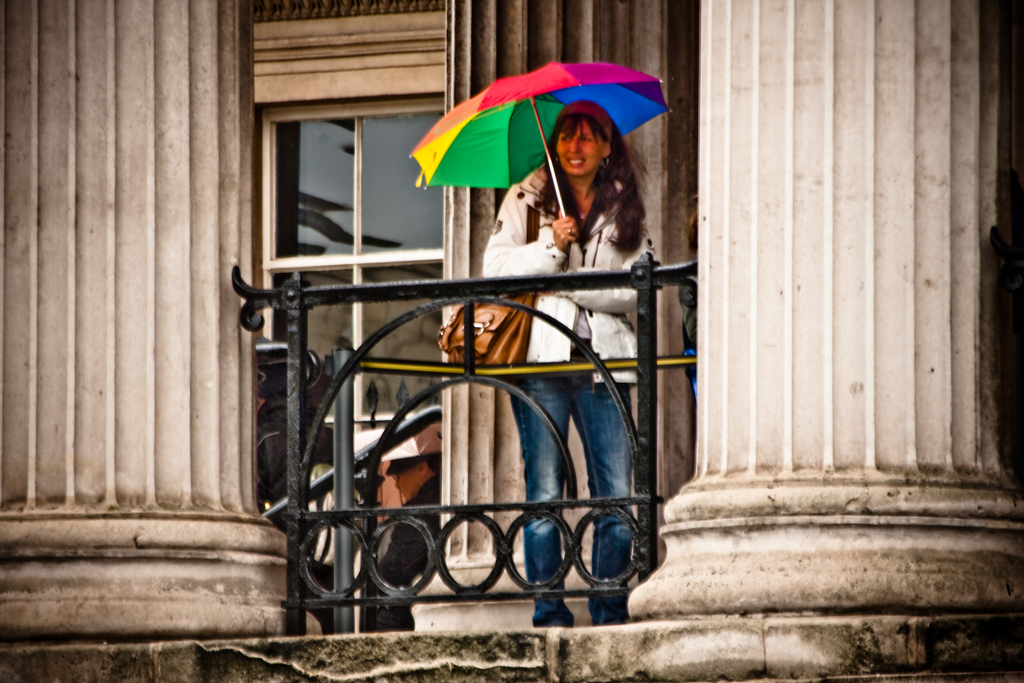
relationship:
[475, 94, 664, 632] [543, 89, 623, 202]
woman has head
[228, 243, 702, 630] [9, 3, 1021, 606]
fence between columns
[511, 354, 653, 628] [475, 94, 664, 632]
jeans on a woman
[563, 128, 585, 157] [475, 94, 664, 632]
nose of a woman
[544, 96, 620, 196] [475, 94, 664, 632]
head of a woman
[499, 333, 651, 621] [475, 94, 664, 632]
jeans on a woman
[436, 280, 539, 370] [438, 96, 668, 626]
bag held by woman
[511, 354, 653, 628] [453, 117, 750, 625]
jeans on woman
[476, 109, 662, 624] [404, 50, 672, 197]
she is carrying an umbrella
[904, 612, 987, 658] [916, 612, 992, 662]
stone has moss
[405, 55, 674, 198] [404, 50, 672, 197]
fabric on an umbrella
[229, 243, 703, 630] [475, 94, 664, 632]
fence near a woman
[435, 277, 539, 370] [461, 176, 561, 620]
bag on a woman's side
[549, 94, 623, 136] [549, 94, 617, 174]
headband on a head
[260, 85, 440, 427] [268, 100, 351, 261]
window with pane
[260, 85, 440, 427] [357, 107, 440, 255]
window with pane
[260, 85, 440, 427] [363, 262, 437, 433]
window with pane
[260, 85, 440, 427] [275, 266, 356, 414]
window with pane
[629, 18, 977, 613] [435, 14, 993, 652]
coulmn on right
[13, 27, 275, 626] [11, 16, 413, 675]
column on left